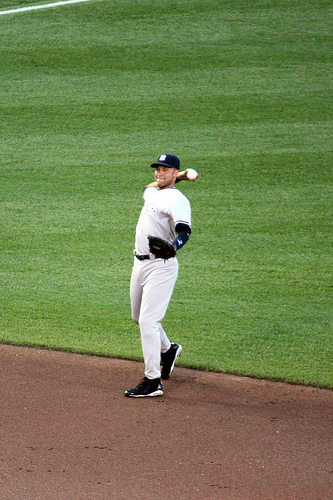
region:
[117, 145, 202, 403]
The player is holding the ball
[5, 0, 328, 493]
The field is dirt and grass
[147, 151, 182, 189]
Player is wearing a hat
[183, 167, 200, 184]
The ball is white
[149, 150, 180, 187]
The hat is blue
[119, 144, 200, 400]
The player is standing on the dirt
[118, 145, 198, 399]
The player is throwing the ball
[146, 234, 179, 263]
The baseball glove is black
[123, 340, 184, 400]
The player is wearing black and white shoes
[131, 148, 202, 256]
The player is wearing a white jersey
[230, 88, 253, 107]
part of a field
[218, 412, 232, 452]
part of a floor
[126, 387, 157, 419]
edge of a shoe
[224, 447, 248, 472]
part of a ground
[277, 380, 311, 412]
edge of a fiedl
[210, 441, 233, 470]
part of a ground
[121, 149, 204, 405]
player is throwing the ball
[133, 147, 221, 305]
player is throwing the ball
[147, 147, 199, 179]
the cap is black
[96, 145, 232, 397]
man in a uniform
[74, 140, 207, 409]
man in baseball uniform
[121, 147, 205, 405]
man holding baseball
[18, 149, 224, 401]
man in a black hat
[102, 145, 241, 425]
man playing baseball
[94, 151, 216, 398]
man wearing black and white cleats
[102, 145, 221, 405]
man throwing baseball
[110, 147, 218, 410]
man wearing a baseball glove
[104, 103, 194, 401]
man wearing a black belt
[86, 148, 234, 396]
man playing defense